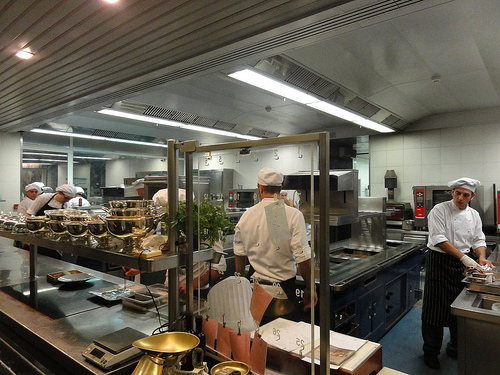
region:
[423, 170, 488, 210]
The cook has on a white hat.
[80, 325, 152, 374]
A scale sits in the corner.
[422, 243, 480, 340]
The man has on a pinstriped apron.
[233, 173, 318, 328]
The man has his back turned.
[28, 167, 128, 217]
A bunch of cooks in the kitchen.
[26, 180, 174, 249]
Silver containers stack together.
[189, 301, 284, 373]
Paper orders hanging from a clip.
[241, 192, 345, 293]
The man is wearing a white cooking coat.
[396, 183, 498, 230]
A conventional oven sits behind the man.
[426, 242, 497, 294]
The man is preparing a dish.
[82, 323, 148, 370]
A gray digital scale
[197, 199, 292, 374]
Papers that have orders written on them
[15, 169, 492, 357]
A group of cooks in the kitchen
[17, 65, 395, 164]
Fluorescent lights in the ceiling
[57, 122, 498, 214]
Tile wall in the background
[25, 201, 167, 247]
Silver bowls on a metal shelf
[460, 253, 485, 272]
Latex glove on chef's hand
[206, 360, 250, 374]
Top of an open can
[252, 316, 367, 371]
Papers on a table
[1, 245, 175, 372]
Silver counter top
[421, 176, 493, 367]
man wearing chef hat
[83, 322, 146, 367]
scale sits on the counter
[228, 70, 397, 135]
fluorescent lights on ceiling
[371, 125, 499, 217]
wall behind man is white tile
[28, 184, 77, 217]
man wearing black apron and chef hat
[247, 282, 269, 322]
pink pieces of paper hang from clips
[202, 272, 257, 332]
chef hat next to the pieces of paper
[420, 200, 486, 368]
man is wearing black pants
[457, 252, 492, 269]
man is wearing white gloves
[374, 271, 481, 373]
floor is blue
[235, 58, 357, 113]
white overhead lighting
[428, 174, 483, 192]
white chef's hat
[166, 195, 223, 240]
large green plant with wide leaves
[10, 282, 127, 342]
shiny silver carving station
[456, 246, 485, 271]
chef wearing white gloves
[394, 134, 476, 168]
white wall with square tiles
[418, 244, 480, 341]
black apron with white stripes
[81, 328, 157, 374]
white and gray food scale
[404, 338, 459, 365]
man wearing black sneakers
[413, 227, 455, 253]
white sleeves on man's shirt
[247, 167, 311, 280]
Chef standing in kitchen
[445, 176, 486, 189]
White round chefs hat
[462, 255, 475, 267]
Man wearing white glove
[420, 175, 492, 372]
Chef preparing food to cook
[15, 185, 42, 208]
Chef is looking at the camera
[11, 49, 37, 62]
A ceiling light is on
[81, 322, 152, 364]
a weight scale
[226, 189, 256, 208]
Microwave in the chefs kitchen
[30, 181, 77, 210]
Chef wearing an apron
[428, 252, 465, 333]
Chef wearing black striped apron